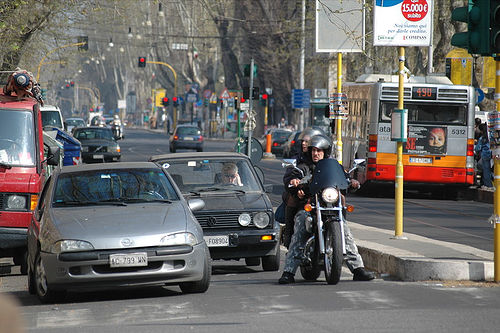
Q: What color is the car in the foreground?
A: Gray.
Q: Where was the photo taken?
A: A street.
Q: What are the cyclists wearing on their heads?
A: Helmets.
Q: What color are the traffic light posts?
A: Yellow.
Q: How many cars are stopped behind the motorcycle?
A: 1.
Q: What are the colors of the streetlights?
A: Red.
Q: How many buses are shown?
A: 1.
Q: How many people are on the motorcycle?
A: 2.